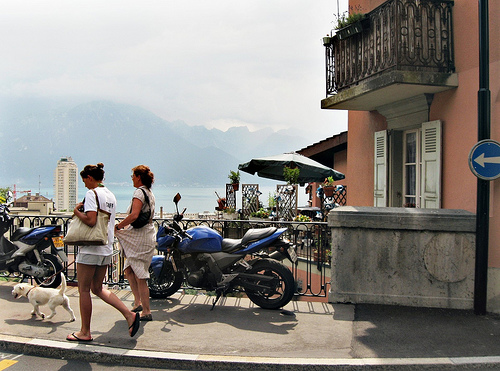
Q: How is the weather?
A: Cloudy.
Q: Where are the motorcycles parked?
A: On the sidewalk.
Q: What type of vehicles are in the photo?
A: Motorcycles.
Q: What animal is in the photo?
A: A dog.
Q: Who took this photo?
A: A tourist.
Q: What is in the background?
A: Buildings.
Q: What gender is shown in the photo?
A: Female.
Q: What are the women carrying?
A: Purses.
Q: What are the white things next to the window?
A: Shutters.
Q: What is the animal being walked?
A: Dog.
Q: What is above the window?
A: The balcony.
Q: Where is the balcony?
A: Above the window.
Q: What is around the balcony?
A: Railing.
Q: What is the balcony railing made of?
A: Metal.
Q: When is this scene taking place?
A: Daytime.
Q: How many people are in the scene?
A: Two.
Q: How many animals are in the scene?
A: One.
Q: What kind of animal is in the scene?
A: Dog.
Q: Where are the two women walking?
A: Sidewalk.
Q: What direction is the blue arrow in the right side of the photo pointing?
A: Left.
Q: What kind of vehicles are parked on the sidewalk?
A: Motorcycles.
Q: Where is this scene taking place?
A: On the sidewalk.